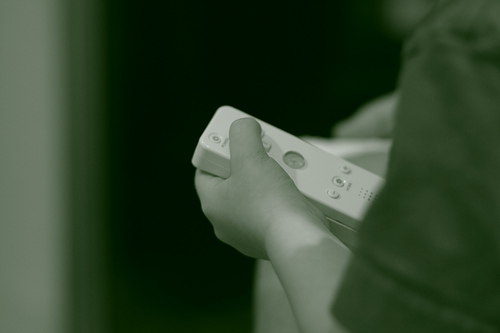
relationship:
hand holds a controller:
[193, 117, 330, 259] [190, 105, 386, 249]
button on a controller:
[282, 150, 307, 171] [194, 96, 384, 237]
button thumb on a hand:
[229, 117, 271, 160] [171, 116, 328, 256]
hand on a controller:
[171, 116, 328, 256] [190, 102, 385, 246]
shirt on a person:
[327, 0, 500, 333] [330, 0, 500, 333]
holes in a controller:
[352, 182, 377, 201] [194, 96, 384, 237]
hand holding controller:
[193, 117, 330, 259] [194, 96, 384, 237]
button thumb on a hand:
[229, 117, 271, 160] [193, 117, 330, 259]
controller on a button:
[194, 96, 384, 237] [274, 141, 309, 174]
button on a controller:
[339, 153, 357, 175] [194, 96, 384, 237]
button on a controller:
[330, 171, 352, 188] [194, 96, 384, 237]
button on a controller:
[328, 189, 339, 198] [194, 96, 384, 237]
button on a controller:
[208, 130, 221, 142] [190, 105, 386, 249]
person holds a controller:
[330, 0, 500, 333] [190, 105, 386, 249]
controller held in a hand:
[190, 105, 386, 249] [193, 117, 330, 259]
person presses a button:
[330, 3, 497, 323] [256, 134, 275, 153]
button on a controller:
[256, 134, 275, 153] [190, 105, 386, 249]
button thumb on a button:
[229, 117, 271, 160] [203, 125, 225, 151]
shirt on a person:
[325, 50, 496, 333] [151, 90, 431, 327]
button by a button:
[340, 162, 353, 179] [330, 173, 346, 189]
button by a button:
[330, 173, 346, 189] [327, 183, 343, 200]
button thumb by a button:
[229, 117, 271, 160] [255, 133, 273, 155]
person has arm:
[330, 0, 500, 333] [243, 210, 352, 302]